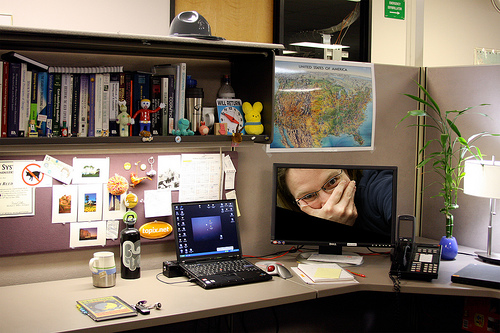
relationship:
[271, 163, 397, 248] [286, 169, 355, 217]
monitor displays man's face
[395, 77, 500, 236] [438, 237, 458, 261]
plant inside of vase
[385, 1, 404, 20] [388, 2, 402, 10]
sign has lettering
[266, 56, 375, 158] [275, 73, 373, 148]
map displays united states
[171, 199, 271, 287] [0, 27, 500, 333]
laptop on top of desk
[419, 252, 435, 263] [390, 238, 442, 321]
note on top of phone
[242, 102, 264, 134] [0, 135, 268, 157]
bunny on top of shelf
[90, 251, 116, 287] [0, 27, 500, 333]
cup on top of desk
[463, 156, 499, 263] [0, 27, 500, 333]
lamp on top of desk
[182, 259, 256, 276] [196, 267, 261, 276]
keyboard has edge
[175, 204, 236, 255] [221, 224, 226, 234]
screen has part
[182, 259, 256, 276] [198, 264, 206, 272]
keyboard has part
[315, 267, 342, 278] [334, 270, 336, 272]
paper has part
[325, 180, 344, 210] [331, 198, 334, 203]
finger has part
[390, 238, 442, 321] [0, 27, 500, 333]
phone on top of desk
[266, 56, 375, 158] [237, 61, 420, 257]
map on wall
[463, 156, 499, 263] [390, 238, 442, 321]
lamp next to phone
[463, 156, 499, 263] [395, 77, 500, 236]
lamp next to plant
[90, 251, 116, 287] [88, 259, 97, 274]
cup has handle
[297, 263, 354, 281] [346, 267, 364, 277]
notebook next to pen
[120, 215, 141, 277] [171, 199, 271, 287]
flask next to laptop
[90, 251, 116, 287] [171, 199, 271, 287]
cup next to laptop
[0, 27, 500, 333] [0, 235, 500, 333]
desk has surface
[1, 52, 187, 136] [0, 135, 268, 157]
books are on top of shelf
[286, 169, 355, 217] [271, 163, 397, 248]
man's face on monitor